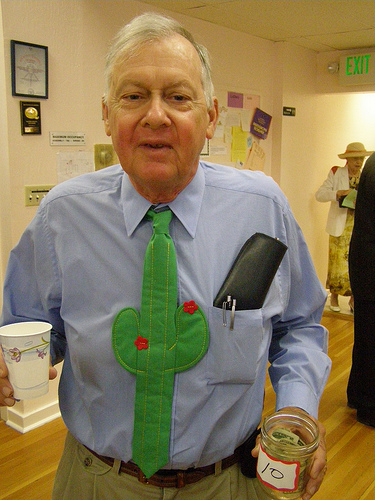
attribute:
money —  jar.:
[245, 407, 327, 486]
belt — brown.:
[90, 445, 225, 487]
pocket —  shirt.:
[200, 296, 272, 382]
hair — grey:
[110, 12, 161, 41]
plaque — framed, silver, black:
[13, 39, 50, 96]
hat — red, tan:
[330, 138, 369, 158]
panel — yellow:
[21, 186, 59, 211]